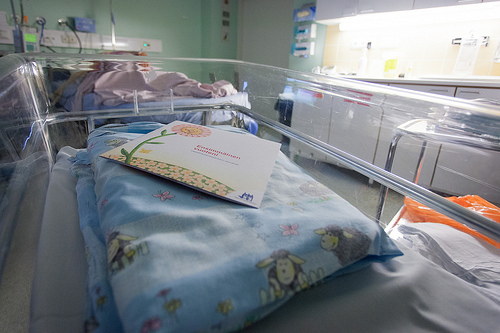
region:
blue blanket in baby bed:
[58, 104, 338, 331]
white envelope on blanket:
[107, 95, 308, 225]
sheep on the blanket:
[235, 214, 389, 306]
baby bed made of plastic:
[0, 21, 499, 286]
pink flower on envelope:
[145, 111, 215, 148]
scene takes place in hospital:
[0, 0, 497, 312]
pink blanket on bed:
[94, 51, 241, 116]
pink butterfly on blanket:
[268, 213, 311, 244]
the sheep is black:
[310, 219, 377, 268]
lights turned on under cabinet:
[330, 7, 497, 57]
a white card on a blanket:
[90, 86, 289, 220]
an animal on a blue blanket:
[237, 230, 329, 331]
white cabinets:
[287, 60, 429, 162]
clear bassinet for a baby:
[6, 32, 496, 307]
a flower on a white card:
[119, 111, 212, 181]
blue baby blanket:
[39, 102, 379, 330]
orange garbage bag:
[390, 150, 499, 232]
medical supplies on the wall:
[2, 12, 124, 64]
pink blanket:
[82, 49, 234, 118]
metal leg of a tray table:
[350, 123, 429, 239]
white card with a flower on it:
[111, 96, 320, 252]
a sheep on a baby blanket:
[240, 225, 320, 313]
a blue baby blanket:
[43, 102, 398, 331]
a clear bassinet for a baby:
[8, 32, 479, 330]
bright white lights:
[325, 8, 487, 67]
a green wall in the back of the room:
[165, 22, 210, 72]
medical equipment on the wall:
[0, 13, 137, 48]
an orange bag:
[390, 166, 498, 246]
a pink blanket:
[59, 40, 196, 118]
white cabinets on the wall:
[294, 73, 422, 170]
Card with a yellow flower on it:
[104, 123, 276, 208]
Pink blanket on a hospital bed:
[96, 61, 223, 99]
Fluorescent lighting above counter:
[331, 0, 494, 34]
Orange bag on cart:
[437, 187, 498, 241]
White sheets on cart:
[408, 219, 487, 286]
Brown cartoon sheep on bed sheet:
[250, 242, 313, 292]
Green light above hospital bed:
[140, 38, 157, 53]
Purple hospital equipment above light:
[60, 10, 97, 37]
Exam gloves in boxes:
[287, 16, 317, 57]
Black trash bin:
[271, 81, 297, 141]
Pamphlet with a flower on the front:
[150, 110, 284, 214]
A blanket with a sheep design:
[85, 137, 363, 309]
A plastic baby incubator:
[5, 36, 497, 274]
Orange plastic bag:
[410, 174, 498, 236]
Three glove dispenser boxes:
[280, 7, 316, 62]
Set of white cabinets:
[295, 75, 479, 187]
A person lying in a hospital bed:
[56, 47, 247, 122]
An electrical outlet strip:
[12, 29, 159, 56]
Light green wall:
[152, 10, 210, 53]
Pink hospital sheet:
[96, 71, 209, 94]